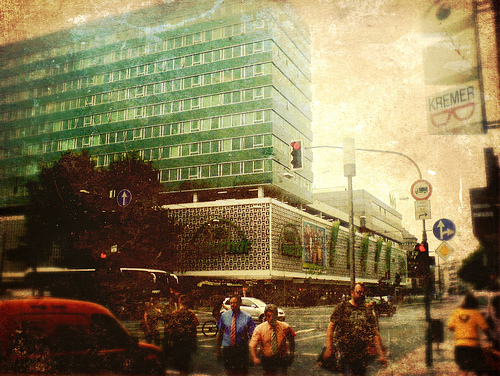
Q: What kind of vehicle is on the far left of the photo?
A: Minivan.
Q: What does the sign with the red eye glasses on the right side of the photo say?
A: Kremer.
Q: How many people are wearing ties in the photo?
A: Two.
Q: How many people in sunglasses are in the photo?
A: One.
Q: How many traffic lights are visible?
A: One.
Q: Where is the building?
A: Background.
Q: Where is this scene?
A: City scene.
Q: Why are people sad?
A: They have been rained on.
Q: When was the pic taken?
A: In the evening.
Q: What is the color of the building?
A: Green.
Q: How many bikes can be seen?
A: 1.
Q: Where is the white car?
A: On the road.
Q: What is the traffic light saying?
A: Stop.